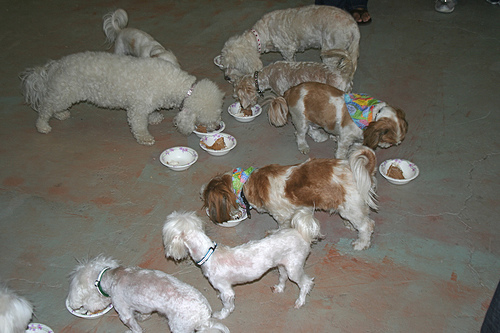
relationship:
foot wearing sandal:
[352, 9, 370, 23] [350, 7, 372, 25]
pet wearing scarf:
[268, 78, 409, 163] [340, 91, 389, 131]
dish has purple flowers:
[157, 144, 201, 173] [163, 145, 193, 156]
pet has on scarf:
[268, 78, 409, 163] [340, 91, 389, 131]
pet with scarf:
[268, 78, 409, 163] [340, 91, 389, 131]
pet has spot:
[196, 146, 379, 252] [363, 149, 378, 184]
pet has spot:
[196, 146, 379, 252] [287, 159, 344, 210]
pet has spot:
[196, 146, 379, 252] [336, 171, 351, 183]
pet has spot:
[196, 146, 379, 252] [243, 163, 288, 208]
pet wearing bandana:
[196, 146, 379, 252] [226, 165, 259, 209]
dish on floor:
[157, 144, 201, 173] [1, 2, 498, 332]